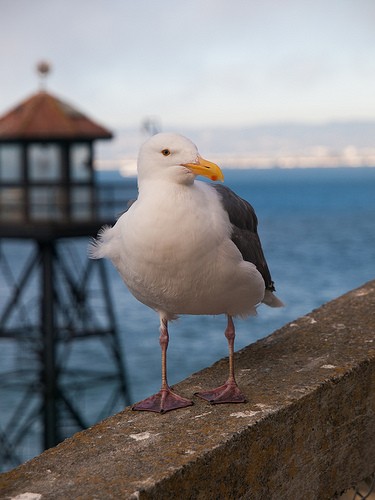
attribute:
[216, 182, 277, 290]
wing — black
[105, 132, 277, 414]
bird — blue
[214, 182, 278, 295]
feathers — gray 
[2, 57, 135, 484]
tower — brown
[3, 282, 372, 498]
rail — iron , Dirty , rusted 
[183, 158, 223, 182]
beak — orange 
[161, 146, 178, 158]
eye — small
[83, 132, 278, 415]
bird — White 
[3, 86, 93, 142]
roof — orange 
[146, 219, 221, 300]
breast — white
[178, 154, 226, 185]
beak — yellow 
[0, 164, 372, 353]
ocean — blue , clear 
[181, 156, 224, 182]
beak — orange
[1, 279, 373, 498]
ledge — dark brown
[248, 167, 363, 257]
water — blue 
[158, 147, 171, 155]
eye — black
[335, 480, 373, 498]
fence — silver